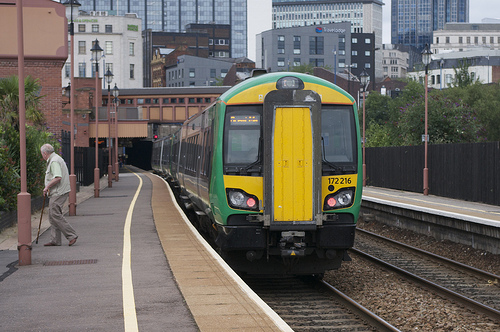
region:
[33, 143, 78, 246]
Man walking and holding cane in hand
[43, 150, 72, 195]
White short sleeved shirt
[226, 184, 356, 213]
Headlights on front of train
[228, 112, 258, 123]
Lights showing through window inside train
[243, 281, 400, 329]
Train tracks in front of train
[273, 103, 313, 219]
Yellow panel on front of train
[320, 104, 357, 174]
Large window on front of train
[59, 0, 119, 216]
Group of street lights on side of train tracks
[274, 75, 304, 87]
Sign on top of train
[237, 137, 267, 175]
Windshield wiper on train window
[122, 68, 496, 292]
a train on the tracks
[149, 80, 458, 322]
a passenger train on the tracks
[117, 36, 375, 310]
a green and yellow train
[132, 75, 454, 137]
a green and yellow train on the tacks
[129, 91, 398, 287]
a green and yellow passenger train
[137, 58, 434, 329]
green and yellow passenger train on tracks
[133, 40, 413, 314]
tracks with a train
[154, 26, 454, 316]
tracks with a passenger train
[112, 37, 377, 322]
tracks with a yellow and green train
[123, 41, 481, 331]
trains on train tracks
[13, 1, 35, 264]
tall red metal pole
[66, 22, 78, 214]
tall red metal pole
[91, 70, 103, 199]
tall red metal pole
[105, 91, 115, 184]
tall red metal pole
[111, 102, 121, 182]
tall red metal pole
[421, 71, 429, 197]
tall red metal pole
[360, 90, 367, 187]
tall red metal pole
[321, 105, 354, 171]
glass window on train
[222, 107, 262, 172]
glass window on train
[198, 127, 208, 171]
glass window on train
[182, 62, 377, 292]
A green and yellow train.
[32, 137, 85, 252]
A man walking with a cane.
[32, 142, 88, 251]
A man wearing khaki pants.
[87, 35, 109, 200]
A painted street light.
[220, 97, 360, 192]
Windows on the front of a train.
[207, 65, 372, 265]
The train has headlights.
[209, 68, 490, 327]
A train on train tracks.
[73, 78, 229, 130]
An overhead walkway for pedestrians.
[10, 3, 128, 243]
A row of painted street lights.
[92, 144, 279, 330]
A sidewalk next to train tracks.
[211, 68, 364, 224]
Front of the train is green and yellow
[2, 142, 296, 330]
Man on the train platform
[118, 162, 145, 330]
White line on the platform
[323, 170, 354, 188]
Numbers 172216 on the train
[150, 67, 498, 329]
A train on train tracks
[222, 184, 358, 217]
Two headlights on the train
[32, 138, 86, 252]
Man is holding a cane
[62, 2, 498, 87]
Many buildings in the background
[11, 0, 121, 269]
Street lamps in a row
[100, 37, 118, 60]
A window on a building